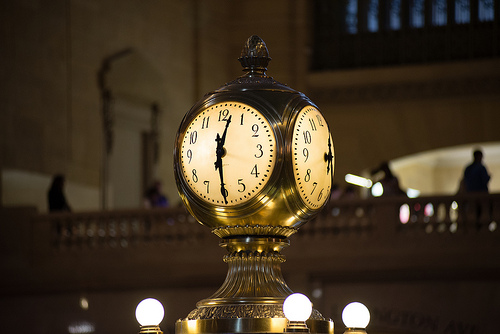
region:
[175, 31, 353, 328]
brass clock fixture in train station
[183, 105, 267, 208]
lit round white clock face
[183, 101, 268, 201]
black numerals on clock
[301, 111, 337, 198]
black numerals on clock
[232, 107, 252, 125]
number on a clock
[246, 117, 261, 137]
number on a clock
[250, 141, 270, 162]
number on a clock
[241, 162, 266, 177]
number on a clock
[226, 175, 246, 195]
number on a clock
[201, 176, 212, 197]
number on a clock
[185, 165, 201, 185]
number on a clock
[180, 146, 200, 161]
number on a clock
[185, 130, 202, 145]
number on a clock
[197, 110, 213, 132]
number on a clock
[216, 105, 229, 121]
the number 12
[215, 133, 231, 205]
the big hand on the clock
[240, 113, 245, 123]
the number 1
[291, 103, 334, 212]
the clock facing right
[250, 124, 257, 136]
the number 2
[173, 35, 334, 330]
the clock is gold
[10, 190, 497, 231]
the rail in the back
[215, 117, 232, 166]
the little hand on the clock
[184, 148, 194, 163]
the number 9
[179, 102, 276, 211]
Most visible clock face.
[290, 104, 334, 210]
Not as visible illuminated clock face.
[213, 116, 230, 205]
Black hands of the most visible clock.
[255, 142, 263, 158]
Black number 3 on a clock.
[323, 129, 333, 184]
Black hands on the less visible clock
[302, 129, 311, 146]
Number 10 on the less visible clock.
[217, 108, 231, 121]
Number 12 on a more visible clock.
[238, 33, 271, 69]
Pointy gold top of a clock.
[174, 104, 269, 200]
Black and white clock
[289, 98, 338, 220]
Black and white clock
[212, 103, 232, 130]
Black number on a white clock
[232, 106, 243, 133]
Black number on a white clock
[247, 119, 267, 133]
Black number on a white clock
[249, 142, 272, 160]
Black number on a white clock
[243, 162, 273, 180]
Black number on a white clock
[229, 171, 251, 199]
Black number on a white clock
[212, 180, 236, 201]
Black number on a white clock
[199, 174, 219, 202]
Black number on a white clock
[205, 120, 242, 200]
The hands of the clock facing forward.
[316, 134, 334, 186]
The hands of the clock facing right.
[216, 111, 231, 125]
The number 12 on the clock facing forward.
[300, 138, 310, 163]
The number 9 on the clock facing right.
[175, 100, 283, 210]
clock on the light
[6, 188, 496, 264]
Railing in the building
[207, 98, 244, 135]
number on the clock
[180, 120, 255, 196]
hands on the clock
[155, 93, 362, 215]
two faces of the clocks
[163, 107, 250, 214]
hands on the golden clock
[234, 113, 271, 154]
the number 2 on clock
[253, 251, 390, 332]
lights below the clock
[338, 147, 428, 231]
person on the balcony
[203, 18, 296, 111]
top of the clock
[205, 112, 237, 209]
a pair of black metal arrows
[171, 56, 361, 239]
a decorative piece with round clocks on all sides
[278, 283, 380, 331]
a pair of lit up light bulbs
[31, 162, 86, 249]
a person leaning against the fence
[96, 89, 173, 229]
a white door way in the wall